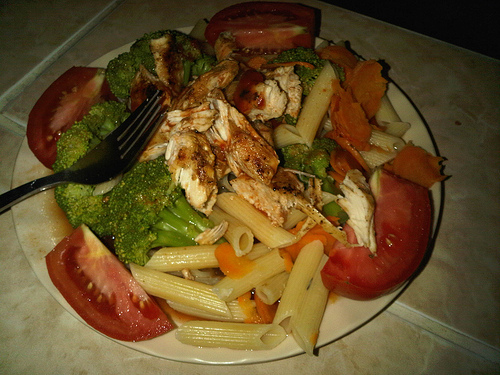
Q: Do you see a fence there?
A: No, there are no fences.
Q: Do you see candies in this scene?
A: No, there are no candies.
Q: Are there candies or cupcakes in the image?
A: No, there are no candies or cupcakes.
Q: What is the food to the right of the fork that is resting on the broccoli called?
A: The food is tuna.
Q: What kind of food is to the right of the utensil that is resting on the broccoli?
A: The food is tuna.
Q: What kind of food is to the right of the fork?
A: The food is tuna.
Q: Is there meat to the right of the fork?
A: No, there is tuna to the right of the fork.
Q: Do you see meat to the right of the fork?
A: No, there is tuna to the right of the fork.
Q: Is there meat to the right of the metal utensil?
A: No, there is tuna to the right of the fork.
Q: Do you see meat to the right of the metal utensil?
A: No, there is tuna to the right of the fork.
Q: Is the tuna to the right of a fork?
A: Yes, the tuna is to the right of a fork.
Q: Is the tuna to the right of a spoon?
A: No, the tuna is to the right of a fork.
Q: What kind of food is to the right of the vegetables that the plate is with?
A: The food is tuna.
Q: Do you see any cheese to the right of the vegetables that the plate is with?
A: No, there is tuna to the right of the veggies.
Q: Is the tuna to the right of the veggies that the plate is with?
A: Yes, the tuna is to the right of the veggies.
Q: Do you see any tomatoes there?
A: Yes, there is a tomato.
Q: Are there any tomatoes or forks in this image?
A: Yes, there is a tomato.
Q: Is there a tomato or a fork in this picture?
A: Yes, there is a tomato.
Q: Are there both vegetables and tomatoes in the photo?
A: Yes, there are both a tomato and vegetables.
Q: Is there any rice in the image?
A: No, there is no rice.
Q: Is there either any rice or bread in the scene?
A: No, there are no rice or breads.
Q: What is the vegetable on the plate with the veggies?
A: The vegetable is a tomato.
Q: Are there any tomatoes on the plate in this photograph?
A: Yes, there is a tomato on the plate.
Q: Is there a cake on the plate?
A: No, there is a tomato on the plate.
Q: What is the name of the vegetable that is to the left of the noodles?
A: The vegetable is a tomato.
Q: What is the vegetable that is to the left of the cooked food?
A: The vegetable is a tomato.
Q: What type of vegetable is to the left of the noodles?
A: The vegetable is a tomato.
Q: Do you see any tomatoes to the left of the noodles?
A: Yes, there is a tomato to the left of the noodles.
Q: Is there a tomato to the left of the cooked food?
A: Yes, there is a tomato to the left of the noodles.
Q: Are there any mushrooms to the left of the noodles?
A: No, there is a tomato to the left of the noodles.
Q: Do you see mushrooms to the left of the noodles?
A: No, there is a tomato to the left of the noodles.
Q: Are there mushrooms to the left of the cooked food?
A: No, there is a tomato to the left of the noodles.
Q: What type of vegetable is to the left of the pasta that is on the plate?
A: The vegetable is a tomato.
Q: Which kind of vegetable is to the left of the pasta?
A: The vegetable is a tomato.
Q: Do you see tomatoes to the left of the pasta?
A: Yes, there is a tomato to the left of the pasta.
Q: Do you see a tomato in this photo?
A: Yes, there is a tomato.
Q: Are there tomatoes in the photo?
A: Yes, there is a tomato.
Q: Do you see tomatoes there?
A: Yes, there is a tomato.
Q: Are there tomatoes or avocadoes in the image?
A: Yes, there is a tomato.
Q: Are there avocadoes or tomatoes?
A: Yes, there is a tomato.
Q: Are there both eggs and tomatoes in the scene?
A: No, there is a tomato but no eggs.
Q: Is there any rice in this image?
A: No, there is no rice.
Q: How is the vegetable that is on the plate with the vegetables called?
A: The vegetable is a tomato.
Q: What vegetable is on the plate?
A: The vegetable is a tomato.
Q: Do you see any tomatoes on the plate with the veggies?
A: Yes, there is a tomato on the plate.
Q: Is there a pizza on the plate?
A: No, there is a tomato on the plate.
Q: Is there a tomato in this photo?
A: Yes, there is a tomato.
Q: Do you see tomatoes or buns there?
A: Yes, there is a tomato.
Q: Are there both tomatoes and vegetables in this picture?
A: Yes, there are both a tomato and vegetables.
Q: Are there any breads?
A: No, there are no breads.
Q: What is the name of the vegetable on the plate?
A: The vegetable is a tomato.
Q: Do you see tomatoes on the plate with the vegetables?
A: Yes, there is a tomato on the plate.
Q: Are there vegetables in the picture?
A: Yes, there are vegetables.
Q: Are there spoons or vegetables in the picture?
A: Yes, there are vegetables.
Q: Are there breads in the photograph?
A: No, there are no breads.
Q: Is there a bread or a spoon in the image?
A: No, there are no breads or spoons.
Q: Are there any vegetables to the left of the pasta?
A: Yes, there are vegetables to the left of the pasta.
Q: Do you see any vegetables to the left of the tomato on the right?
A: Yes, there are vegetables to the left of the tomato.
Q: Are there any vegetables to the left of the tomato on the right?
A: Yes, there are vegetables to the left of the tomato.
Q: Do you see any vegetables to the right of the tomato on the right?
A: No, the vegetables are to the left of the tomato.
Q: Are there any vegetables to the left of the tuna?
A: Yes, there are vegetables to the left of the tuna.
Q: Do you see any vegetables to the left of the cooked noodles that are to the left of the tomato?
A: Yes, there are vegetables to the left of the noodles.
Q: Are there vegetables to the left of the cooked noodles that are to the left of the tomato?
A: Yes, there are vegetables to the left of the noodles.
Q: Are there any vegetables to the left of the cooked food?
A: Yes, there are vegetables to the left of the noodles.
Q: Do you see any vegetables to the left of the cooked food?
A: Yes, there are vegetables to the left of the noodles.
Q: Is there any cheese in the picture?
A: No, there is no cheese.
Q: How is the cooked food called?
A: The food is noodles.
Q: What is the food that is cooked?
A: The food is noodles.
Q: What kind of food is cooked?
A: The food is noodles.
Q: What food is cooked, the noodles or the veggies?
A: The noodles is cooked.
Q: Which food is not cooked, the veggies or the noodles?
A: The veggies is not cooked.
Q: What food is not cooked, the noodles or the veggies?
A: The veggies is not cooked.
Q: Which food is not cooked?
A: The food is vegetables.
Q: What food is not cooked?
A: The food is vegetables.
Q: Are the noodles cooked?
A: Yes, the noodles are cooked.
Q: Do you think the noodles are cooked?
A: Yes, the noodles are cooked.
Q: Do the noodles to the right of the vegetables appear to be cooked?
A: Yes, the noodles are cooked.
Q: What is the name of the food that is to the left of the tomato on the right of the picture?
A: The food is noodles.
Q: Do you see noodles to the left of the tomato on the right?
A: Yes, there are noodles to the left of the tomato.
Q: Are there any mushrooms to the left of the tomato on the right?
A: No, there are noodles to the left of the tomato.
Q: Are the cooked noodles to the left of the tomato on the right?
A: Yes, the noodles are to the left of the tomato.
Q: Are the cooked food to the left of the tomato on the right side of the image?
A: Yes, the noodles are to the left of the tomato.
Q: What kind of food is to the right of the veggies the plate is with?
A: The food is noodles.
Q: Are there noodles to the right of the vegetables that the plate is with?
A: Yes, there are noodles to the right of the vegetables.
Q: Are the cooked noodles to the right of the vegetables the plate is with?
A: Yes, the noodles are to the right of the veggies.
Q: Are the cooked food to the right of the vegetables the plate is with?
A: Yes, the noodles are to the right of the veggies.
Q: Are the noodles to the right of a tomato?
A: Yes, the noodles are to the right of a tomato.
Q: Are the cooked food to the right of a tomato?
A: Yes, the noodles are to the right of a tomato.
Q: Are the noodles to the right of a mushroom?
A: No, the noodles are to the right of a tomato.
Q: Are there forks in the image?
A: Yes, there is a fork.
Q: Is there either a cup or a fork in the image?
A: Yes, there is a fork.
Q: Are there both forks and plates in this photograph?
A: Yes, there are both a fork and a plate.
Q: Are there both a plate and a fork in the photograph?
A: Yes, there are both a fork and a plate.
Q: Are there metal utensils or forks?
A: Yes, there is a metal fork.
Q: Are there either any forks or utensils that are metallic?
A: Yes, the fork is metallic.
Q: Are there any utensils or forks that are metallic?
A: Yes, the fork is metallic.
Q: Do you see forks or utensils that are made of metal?
A: Yes, the fork is made of metal.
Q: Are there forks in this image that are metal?
A: Yes, there is a metal fork.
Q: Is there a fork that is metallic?
A: Yes, there is a fork that is metallic.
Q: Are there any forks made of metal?
A: Yes, there is a fork that is made of metal.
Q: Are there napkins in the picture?
A: No, there are no napkins.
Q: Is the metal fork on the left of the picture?
A: Yes, the fork is on the left of the image.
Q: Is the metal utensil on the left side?
A: Yes, the fork is on the left of the image.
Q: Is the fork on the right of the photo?
A: No, the fork is on the left of the image.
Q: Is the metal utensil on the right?
A: No, the fork is on the left of the image.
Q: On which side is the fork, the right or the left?
A: The fork is on the left of the image.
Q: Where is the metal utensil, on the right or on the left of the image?
A: The fork is on the left of the image.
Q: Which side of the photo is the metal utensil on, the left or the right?
A: The fork is on the left of the image.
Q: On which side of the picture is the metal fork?
A: The fork is on the left of the image.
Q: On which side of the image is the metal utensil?
A: The fork is on the left of the image.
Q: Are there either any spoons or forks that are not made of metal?
A: No, there is a fork but it is made of metal.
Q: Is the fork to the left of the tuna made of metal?
A: Yes, the fork is made of metal.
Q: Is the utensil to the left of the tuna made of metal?
A: Yes, the fork is made of metal.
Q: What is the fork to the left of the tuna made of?
A: The fork is made of metal.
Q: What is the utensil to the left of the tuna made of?
A: The fork is made of metal.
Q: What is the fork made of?
A: The fork is made of metal.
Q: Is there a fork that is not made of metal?
A: No, there is a fork but it is made of metal.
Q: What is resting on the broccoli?
A: The fork is resting on the broccoli.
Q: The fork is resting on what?
A: The fork is resting on the broccoli.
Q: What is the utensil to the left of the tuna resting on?
A: The fork is resting on the broccoli.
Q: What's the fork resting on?
A: The fork is resting on the broccoli.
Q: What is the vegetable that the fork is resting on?
A: The vegetable is broccoli.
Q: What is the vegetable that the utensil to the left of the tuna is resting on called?
A: The vegetable is broccoli.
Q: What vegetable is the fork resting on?
A: The fork is resting on the broccoli.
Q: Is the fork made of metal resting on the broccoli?
A: Yes, the fork is resting on the broccoli.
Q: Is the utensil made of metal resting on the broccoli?
A: Yes, the fork is resting on the broccoli.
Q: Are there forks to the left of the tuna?
A: Yes, there is a fork to the left of the tuna.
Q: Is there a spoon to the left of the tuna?
A: No, there is a fork to the left of the tuna.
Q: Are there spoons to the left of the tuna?
A: No, there is a fork to the left of the tuna.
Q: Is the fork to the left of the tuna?
A: Yes, the fork is to the left of the tuna.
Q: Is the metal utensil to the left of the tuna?
A: Yes, the fork is to the left of the tuna.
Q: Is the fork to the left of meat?
A: No, the fork is to the left of the tuna.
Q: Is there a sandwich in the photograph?
A: No, there are no sandwiches.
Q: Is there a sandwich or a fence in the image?
A: No, there are no sandwiches or fences.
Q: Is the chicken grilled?
A: Yes, the chicken is grilled.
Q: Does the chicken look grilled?
A: Yes, the chicken is grilled.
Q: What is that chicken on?
A: The chicken is on the plate.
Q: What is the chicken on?
A: The chicken is on the plate.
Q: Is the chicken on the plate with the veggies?
A: Yes, the chicken is on the plate.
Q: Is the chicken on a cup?
A: No, the chicken is on the plate.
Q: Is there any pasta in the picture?
A: Yes, there is pasta.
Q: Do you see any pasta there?
A: Yes, there is pasta.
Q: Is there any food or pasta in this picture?
A: Yes, there is pasta.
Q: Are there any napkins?
A: No, there are no napkins.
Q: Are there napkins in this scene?
A: No, there are no napkins.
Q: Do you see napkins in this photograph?
A: No, there are no napkins.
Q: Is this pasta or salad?
A: This is pasta.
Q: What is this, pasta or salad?
A: This is pasta.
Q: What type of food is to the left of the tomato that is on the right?
A: The food is pasta.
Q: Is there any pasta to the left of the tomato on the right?
A: Yes, there is pasta to the left of the tomato.